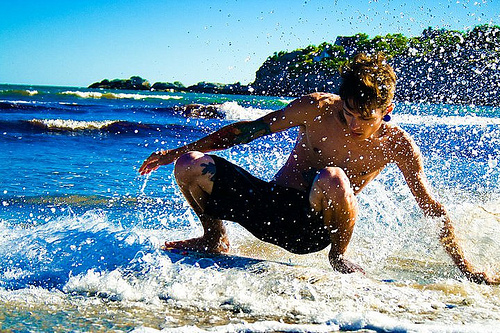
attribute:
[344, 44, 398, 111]
hair — BRIGHT, BROWN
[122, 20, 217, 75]
sky — blue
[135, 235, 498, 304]
board — SKIM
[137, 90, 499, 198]
waves — WHITE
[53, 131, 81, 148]
color — VERY BRIGHT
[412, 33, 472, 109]
trees — GREEN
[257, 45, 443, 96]
trees — GREEN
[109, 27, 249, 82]
clouds — white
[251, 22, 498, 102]
trees — GREEN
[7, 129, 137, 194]
water — BLUE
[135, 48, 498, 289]
surfer — young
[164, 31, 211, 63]
clouds — white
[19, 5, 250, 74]
sky — blue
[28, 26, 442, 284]
photo — RATHER STUNNING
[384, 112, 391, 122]
ear lobe — STRECHED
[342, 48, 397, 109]
hair — FULL 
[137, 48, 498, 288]
man — Surfing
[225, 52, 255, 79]
clouds — white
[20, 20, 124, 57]
sky — blue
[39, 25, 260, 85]
clouds — white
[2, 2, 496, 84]
sky — blue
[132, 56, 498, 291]
boy — SHIRTLESS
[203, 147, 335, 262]
shorts — black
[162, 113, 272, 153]
tattoos — BRIGHTLY COLORED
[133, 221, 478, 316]
board — SKIM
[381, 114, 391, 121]
gauge — LARGE, BLUE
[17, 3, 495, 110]
sky — blue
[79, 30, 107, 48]
sky — BLUE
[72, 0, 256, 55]
clouds — white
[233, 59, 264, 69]
clouds — white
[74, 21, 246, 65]
sky — blue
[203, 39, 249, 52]
clouds — white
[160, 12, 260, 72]
clouds — WHITE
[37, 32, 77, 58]
clouds — WHITE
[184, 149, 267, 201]
thigh — HIS